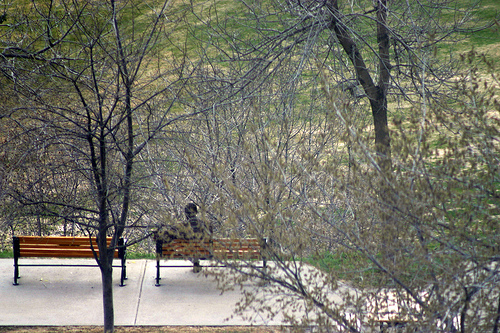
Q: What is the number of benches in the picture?
A: 2.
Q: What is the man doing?
A: Sitting on a bench.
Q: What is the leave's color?
A: Green.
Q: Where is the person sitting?
A: Bench.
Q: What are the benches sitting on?
A: Concrete.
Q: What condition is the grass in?
A: Green.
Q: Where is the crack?
A: Between the benches.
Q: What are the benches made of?
A: Wood.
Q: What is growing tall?
A: Trees.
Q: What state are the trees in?
A: Bare.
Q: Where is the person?
A: Sitting on a bench.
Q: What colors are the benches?
A: Black and brown.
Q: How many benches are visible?
A: Two.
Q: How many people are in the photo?
A: One.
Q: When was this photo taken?
A: During the daytime.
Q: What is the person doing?
A: Sitting.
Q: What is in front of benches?
A: Trees.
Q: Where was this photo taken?
A: In a park.